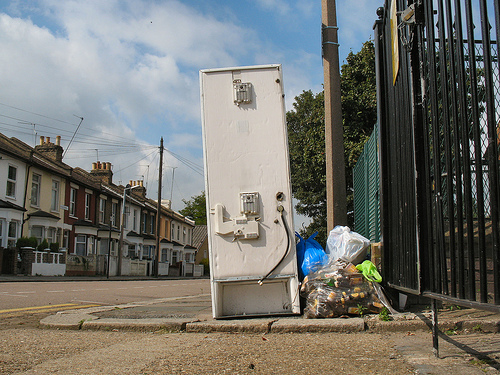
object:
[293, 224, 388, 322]
bag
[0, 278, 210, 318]
sidewalk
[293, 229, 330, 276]
bag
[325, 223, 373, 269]
bag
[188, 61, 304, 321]
box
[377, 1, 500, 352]
fence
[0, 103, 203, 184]
wires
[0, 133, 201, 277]
homes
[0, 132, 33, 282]
home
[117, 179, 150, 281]
home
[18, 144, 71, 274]
home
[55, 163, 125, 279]
home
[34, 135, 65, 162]
chimney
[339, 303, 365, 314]
bottle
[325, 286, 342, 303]
bottle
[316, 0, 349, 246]
pole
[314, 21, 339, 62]
sign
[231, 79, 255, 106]
control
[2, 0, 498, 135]
sky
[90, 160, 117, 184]
chimney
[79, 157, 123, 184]
roof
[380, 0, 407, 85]
sign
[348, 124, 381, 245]
fence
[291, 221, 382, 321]
trash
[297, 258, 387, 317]
bag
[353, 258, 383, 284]
bag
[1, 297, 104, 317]
line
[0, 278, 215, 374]
street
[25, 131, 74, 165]
roof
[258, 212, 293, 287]
cord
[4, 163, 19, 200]
window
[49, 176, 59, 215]
window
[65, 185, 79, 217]
window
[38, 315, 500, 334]
curb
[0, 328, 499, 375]
driveway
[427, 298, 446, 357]
support